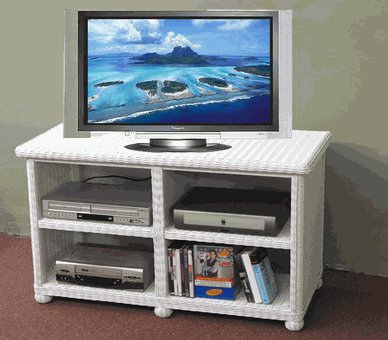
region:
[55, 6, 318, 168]
television is turned on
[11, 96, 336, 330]
white entertainment system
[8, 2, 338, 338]
television on the white stand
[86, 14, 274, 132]
tropical scene on the television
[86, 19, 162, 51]
thick white clouds in the sky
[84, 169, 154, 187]
thin black cord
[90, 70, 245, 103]
islands in the water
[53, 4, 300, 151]
television on the stand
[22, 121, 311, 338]
the stand is white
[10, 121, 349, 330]
the stand made of straw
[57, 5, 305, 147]
the television is on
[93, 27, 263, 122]
islands on the screen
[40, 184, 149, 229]
the dvd vcr combo on the stand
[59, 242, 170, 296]
the vcr on the stand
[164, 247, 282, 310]
the media collection on the stand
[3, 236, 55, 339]
the floor is carpeted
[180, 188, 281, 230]
the media box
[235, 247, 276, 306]
books in a white shelf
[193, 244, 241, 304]
books in a white shelf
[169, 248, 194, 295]
books in a white shelf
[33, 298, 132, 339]
A brown cement floor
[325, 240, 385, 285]
A white house wall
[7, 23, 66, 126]
A white house wall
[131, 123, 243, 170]
this is the tv stand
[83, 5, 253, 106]
the tv is on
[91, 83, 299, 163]
the tv is black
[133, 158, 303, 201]
the shelf is white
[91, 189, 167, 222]
this is a dvd player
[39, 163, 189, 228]
the dvd player is silver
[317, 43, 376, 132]
the wall is gray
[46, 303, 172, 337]
the carpet is red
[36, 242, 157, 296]
Silver VCR in the console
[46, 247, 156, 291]
VCR in the console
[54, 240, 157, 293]
Silver VHS player in the console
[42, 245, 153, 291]
VCR in the white console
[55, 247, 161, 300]
Silver VCR in the white console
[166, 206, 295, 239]
DVR in the console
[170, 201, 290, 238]
Silver DVR in the console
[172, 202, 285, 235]
DVR in the white console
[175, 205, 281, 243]
Silver DVR in the white console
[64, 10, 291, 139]
a television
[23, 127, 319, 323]
a white tv stand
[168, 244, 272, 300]
dvd cases on the shelf